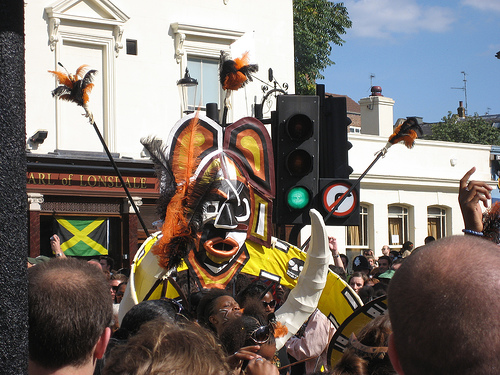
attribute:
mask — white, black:
[195, 179, 259, 239]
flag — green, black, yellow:
[52, 215, 114, 264]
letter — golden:
[30, 165, 157, 190]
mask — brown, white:
[194, 145, 274, 250]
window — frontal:
[184, 55, 221, 119]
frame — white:
[166, 20, 243, 150]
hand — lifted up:
[456, 159, 493, 244]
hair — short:
[410, 290, 470, 342]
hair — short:
[22, 284, 90, 352]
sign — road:
[318, 178, 360, 224]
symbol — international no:
[326, 185, 350, 215]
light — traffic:
[270, 89, 320, 242]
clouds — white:
[329, 3, 489, 49]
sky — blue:
[310, 0, 492, 130]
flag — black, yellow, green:
[45, 213, 110, 258]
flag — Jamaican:
[52, 218, 110, 258]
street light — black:
[272, 92, 322, 224]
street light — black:
[321, 95, 354, 177]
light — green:
[284, 185, 310, 209]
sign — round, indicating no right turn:
[320, 180, 359, 218]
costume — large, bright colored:
[46, 50, 364, 371]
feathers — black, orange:
[214, 53, 262, 95]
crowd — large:
[31, 235, 483, 339]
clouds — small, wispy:
[343, 7, 451, 41]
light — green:
[290, 188, 310, 209]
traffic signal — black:
[268, 94, 326, 232]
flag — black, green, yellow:
[44, 214, 117, 253]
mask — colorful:
[192, 150, 252, 273]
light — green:
[289, 187, 319, 214]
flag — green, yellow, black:
[53, 216, 117, 259]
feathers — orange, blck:
[390, 110, 423, 154]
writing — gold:
[24, 170, 164, 190]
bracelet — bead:
[460, 228, 483, 234]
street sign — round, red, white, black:
[321, 178, 360, 223]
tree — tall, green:
[294, 1, 344, 89]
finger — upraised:
[458, 163, 472, 192]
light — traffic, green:
[269, 87, 323, 226]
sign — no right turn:
[321, 178, 363, 221]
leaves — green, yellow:
[303, 6, 326, 49]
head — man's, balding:
[28, 255, 114, 370]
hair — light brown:
[96, 321, 240, 371]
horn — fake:
[270, 205, 328, 357]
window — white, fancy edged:
[170, 17, 241, 128]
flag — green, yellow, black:
[48, 209, 119, 264]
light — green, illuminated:
[280, 178, 322, 218]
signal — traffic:
[274, 86, 333, 219]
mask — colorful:
[164, 105, 275, 275]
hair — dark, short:
[30, 256, 106, 366]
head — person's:
[222, 311, 280, 371]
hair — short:
[406, 277, 474, 341]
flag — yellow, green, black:
[52, 214, 113, 257]